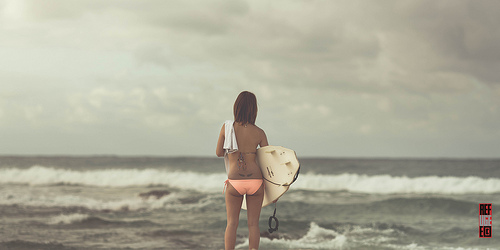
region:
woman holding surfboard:
[201, 81, 320, 249]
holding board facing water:
[195, 70, 320, 248]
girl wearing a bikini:
[199, 68, 314, 248]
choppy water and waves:
[23, 160, 193, 238]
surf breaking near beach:
[17, 133, 199, 243]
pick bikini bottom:
[205, 160, 310, 247]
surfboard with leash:
[235, 137, 315, 245]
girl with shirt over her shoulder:
[201, 81, 328, 247]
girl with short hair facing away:
[185, 78, 325, 248]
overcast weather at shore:
[310, 23, 476, 233]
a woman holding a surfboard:
[207, 86, 311, 245]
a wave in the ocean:
[7, 149, 492, 211]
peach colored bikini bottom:
[210, 175, 286, 202]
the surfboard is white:
[247, 135, 307, 213]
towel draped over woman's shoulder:
[215, 115, 248, 159]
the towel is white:
[208, 114, 242, 161]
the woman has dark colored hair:
[217, 80, 264, 143]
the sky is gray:
[3, 4, 497, 152]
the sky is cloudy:
[7, 5, 496, 164]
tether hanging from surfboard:
[259, 199, 293, 236]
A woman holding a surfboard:
[199, 86, 319, 247]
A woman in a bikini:
[202, 79, 275, 246]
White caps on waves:
[327, 169, 432, 198]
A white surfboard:
[255, 144, 303, 211]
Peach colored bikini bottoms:
[225, 173, 269, 198]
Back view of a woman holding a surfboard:
[204, 86, 303, 246]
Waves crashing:
[14, 159, 183, 222]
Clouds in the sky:
[286, 13, 451, 107]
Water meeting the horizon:
[343, 138, 498, 173]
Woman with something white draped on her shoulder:
[204, 81, 284, 156]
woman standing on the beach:
[182, 78, 334, 249]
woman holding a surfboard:
[177, 76, 319, 243]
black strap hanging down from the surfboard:
[265, 205, 285, 236]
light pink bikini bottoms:
[228, 172, 265, 197]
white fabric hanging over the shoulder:
[216, 111, 246, 155]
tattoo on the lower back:
[232, 168, 261, 180]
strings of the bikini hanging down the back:
[232, 148, 250, 167]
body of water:
[3, 142, 499, 246]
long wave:
[3, 158, 493, 199]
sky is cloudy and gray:
[0, 7, 499, 161]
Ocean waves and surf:
[59, 168, 126, 207]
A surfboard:
[226, 143, 303, 210]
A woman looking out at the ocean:
[214, 87, 272, 248]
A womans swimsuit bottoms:
[224, 176, 266, 197]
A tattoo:
[233, 170, 258, 178]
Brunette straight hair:
[229, 89, 262, 124]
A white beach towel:
[217, 118, 241, 155]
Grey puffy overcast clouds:
[335, 27, 420, 72]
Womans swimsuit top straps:
[228, 146, 254, 171]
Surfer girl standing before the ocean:
[197, 84, 314, 248]